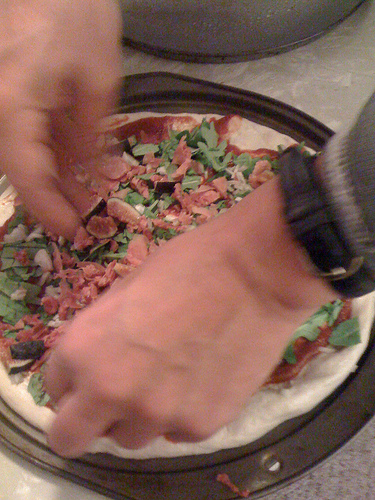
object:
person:
[0, 0, 374, 459]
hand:
[45, 211, 292, 460]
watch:
[275, 144, 375, 300]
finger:
[48, 391, 114, 462]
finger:
[110, 419, 160, 449]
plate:
[120, 2, 366, 64]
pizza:
[0, 113, 375, 461]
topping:
[216, 473, 250, 498]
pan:
[0, 71, 372, 499]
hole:
[264, 458, 280, 471]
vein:
[124, 335, 197, 373]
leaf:
[198, 121, 228, 170]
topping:
[106, 198, 140, 225]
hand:
[0, 1, 124, 243]